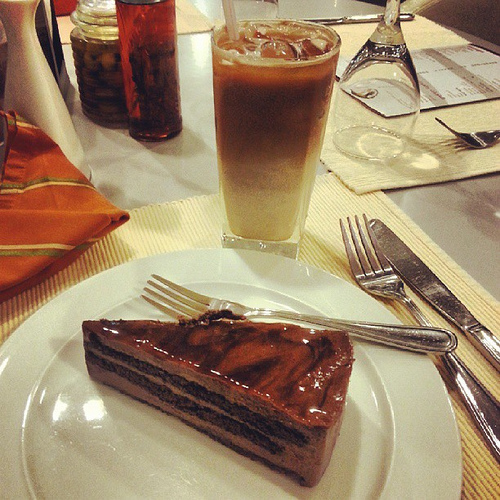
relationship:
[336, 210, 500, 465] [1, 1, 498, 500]
fork on table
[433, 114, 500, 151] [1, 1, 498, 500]
fork on table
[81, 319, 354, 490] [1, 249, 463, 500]
cake on plate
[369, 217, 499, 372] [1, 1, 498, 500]
knife on table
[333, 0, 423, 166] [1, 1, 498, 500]
wine glass on table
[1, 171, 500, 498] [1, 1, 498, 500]
place mat on table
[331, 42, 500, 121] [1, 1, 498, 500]
menu on table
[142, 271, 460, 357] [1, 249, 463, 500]
fork on plate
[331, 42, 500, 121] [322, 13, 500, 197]
menu on place mat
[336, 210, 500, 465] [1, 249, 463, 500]
fork next to plate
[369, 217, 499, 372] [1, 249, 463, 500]
knife next to plate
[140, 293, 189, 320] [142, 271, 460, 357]
prong on fork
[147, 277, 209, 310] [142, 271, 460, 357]
prong on fork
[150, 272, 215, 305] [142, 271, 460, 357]
prong on fork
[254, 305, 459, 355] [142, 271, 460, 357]
handle on fork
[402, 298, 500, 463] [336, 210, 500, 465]
handle on fork